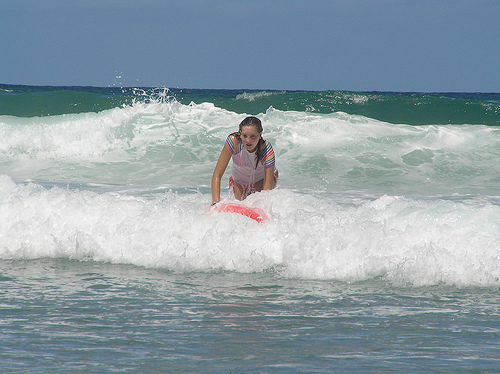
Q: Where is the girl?
A: In the ocean.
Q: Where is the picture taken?
A: The beach.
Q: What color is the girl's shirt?
A: White.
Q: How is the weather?
A: Clear.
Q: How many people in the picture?
A: 1.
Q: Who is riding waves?
A: The girl.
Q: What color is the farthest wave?
A: Green.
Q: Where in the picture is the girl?
A: Center.